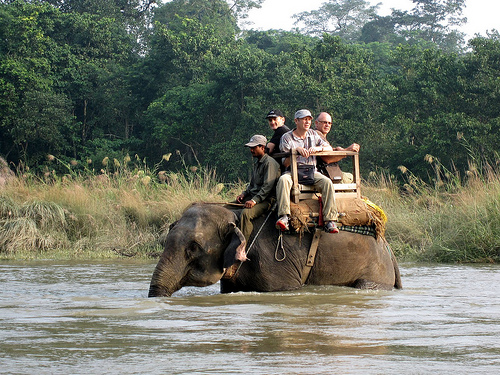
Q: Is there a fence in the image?
A: No, there are no fences.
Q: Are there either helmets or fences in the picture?
A: No, there are no fences or helmets.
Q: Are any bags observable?
A: No, there are no bags.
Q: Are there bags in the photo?
A: No, there are no bags.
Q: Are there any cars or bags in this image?
A: No, there are no bags or cars.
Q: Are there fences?
A: No, there are no fences.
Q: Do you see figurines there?
A: No, there are no figurines.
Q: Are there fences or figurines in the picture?
A: No, there are no figurines or fences.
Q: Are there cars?
A: No, there are no cars.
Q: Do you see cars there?
A: No, there are no cars.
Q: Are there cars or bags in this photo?
A: No, there are no cars or bags.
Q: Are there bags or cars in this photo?
A: No, there are no cars or bags.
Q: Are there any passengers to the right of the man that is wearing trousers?
A: Yes, there are passengers to the right of the man.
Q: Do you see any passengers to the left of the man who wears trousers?
A: No, the passengers are to the right of the man.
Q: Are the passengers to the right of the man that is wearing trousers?
A: Yes, the passengers are to the right of the man.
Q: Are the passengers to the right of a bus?
A: No, the passengers are to the right of the man.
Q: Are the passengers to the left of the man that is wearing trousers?
A: No, the passengers are to the right of the man.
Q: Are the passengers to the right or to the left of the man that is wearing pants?
A: The passengers are to the right of the man.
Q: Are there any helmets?
A: No, there are no helmets.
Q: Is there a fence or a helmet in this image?
A: No, there are no helmets or fences.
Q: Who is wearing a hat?
A: The man is wearing a hat.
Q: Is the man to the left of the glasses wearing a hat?
A: Yes, the man is wearing a hat.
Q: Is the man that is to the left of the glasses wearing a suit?
A: No, the man is wearing a hat.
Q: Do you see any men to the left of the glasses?
A: Yes, there is a man to the left of the glasses.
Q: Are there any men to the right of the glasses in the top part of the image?
A: No, the man is to the left of the glasses.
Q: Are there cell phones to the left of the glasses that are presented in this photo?
A: No, there is a man to the left of the glasses.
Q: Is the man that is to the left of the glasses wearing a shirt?
A: Yes, the man is wearing a shirt.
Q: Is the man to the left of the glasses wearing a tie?
A: No, the man is wearing a shirt.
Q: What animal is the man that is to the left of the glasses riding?
A: The man is riding an elephant.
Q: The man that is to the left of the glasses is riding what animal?
A: The man is riding an elephant.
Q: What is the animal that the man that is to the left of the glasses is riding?
A: The animal is an elephant.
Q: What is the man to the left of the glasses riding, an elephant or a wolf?
A: The man is riding an elephant.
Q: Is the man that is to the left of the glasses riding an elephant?
A: Yes, the man is riding an elephant.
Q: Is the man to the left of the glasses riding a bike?
A: No, the man is riding an elephant.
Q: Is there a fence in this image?
A: No, there are no fences.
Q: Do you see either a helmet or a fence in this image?
A: No, there are no fences or helmets.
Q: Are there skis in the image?
A: No, there are no skis.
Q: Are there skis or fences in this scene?
A: No, there are no skis or fences.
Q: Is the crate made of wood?
A: Yes, the crate is made of wood.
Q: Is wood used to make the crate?
A: Yes, the crate is made of wood.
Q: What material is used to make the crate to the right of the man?
A: The crate is made of wood.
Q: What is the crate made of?
A: The crate is made of wood.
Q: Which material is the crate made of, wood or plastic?
A: The crate is made of wood.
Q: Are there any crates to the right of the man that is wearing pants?
A: Yes, there is a crate to the right of the man.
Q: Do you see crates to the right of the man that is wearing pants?
A: Yes, there is a crate to the right of the man.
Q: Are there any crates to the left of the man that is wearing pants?
A: No, the crate is to the right of the man.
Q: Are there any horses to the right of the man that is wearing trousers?
A: No, there is a crate to the right of the man.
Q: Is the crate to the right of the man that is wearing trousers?
A: Yes, the crate is to the right of the man.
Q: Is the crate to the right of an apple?
A: No, the crate is to the right of the man.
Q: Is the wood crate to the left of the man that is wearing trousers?
A: No, the crate is to the right of the man.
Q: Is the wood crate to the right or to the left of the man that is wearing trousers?
A: The crate is to the right of the man.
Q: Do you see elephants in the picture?
A: Yes, there is an elephant.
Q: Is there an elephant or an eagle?
A: Yes, there is an elephant.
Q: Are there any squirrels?
A: No, there are no squirrels.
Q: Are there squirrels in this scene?
A: No, there are no squirrels.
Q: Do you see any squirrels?
A: No, there are no squirrels.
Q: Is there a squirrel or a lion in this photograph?
A: No, there are no squirrels or lions.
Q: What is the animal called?
A: The animal is an elephant.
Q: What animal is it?
A: The animal is an elephant.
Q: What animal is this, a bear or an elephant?
A: This is an elephant.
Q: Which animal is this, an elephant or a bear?
A: This is an elephant.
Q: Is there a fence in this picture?
A: No, there are no fences.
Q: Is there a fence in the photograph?
A: No, there are no fences.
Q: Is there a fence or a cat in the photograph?
A: No, there are no fences or cats.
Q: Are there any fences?
A: No, there are no fences.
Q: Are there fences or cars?
A: No, there are no fences or cars.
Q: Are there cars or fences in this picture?
A: No, there are no fences or cars.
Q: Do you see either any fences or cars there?
A: No, there are no fences or cars.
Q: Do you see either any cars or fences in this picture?
A: No, there are no fences or cars.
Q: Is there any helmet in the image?
A: No, there are no helmets.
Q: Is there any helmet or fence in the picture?
A: No, there are no helmets or fences.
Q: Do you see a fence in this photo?
A: No, there are no fences.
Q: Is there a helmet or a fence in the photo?
A: No, there are no fences or helmets.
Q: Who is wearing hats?
A: The men are wearing hats.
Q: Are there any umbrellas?
A: No, there are no umbrellas.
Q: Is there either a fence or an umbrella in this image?
A: No, there are no umbrellas or fences.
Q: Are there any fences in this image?
A: No, there are no fences.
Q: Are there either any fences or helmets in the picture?
A: No, there are no fences or helmets.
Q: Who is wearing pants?
A: The man is wearing pants.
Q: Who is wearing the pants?
A: The man is wearing pants.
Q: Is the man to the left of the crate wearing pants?
A: Yes, the man is wearing pants.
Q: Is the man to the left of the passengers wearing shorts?
A: No, the man is wearing pants.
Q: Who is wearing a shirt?
A: The man is wearing a shirt.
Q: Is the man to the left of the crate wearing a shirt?
A: Yes, the man is wearing a shirt.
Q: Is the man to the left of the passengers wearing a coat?
A: No, the man is wearing a shirt.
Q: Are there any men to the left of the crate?
A: Yes, there is a man to the left of the crate.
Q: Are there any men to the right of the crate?
A: No, the man is to the left of the crate.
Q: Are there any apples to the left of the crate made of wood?
A: No, there is a man to the left of the crate.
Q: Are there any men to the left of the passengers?
A: Yes, there is a man to the left of the passengers.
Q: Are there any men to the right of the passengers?
A: No, the man is to the left of the passengers.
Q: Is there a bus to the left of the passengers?
A: No, there is a man to the left of the passengers.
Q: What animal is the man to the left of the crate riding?
A: The man is riding an elephant.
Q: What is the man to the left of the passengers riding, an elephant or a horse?
A: The man is riding an elephant.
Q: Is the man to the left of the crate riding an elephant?
A: Yes, the man is riding an elephant.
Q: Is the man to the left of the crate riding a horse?
A: No, the man is riding an elephant.